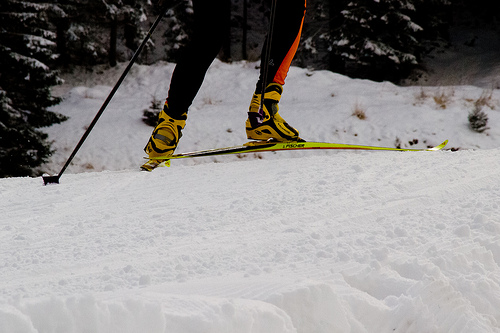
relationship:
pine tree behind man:
[0, 0, 440, 188] [141, 1, 312, 159]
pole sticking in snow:
[38, 0, 175, 188] [0, 56, 497, 330]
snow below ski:
[0, 56, 500, 330] [141, 136, 456, 163]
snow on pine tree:
[30, 34, 49, 43] [0, 0, 440, 188]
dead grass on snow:
[408, 83, 500, 136] [0, 56, 497, 330]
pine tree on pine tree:
[0, 0, 440, 188] [0, 0, 440, 188]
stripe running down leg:
[273, 6, 319, 98] [251, 1, 310, 146]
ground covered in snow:
[121, 200, 371, 266] [0, 168, 493, 325]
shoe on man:
[140, 100, 193, 161] [141, 0, 314, 162]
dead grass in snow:
[408, 83, 500, 136] [0, 56, 497, 330]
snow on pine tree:
[0, 56, 500, 330] [0, 0, 440, 188]